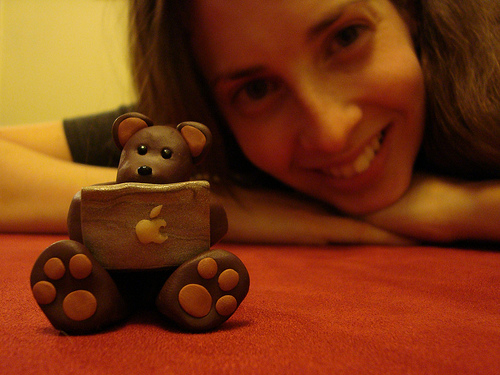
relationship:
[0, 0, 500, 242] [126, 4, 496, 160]
girl has hair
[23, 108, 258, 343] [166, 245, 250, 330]
bear has foot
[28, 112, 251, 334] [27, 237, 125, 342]
bear has foot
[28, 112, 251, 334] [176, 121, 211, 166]
bear has ceramic ear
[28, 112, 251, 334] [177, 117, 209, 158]
bear has ceramic ear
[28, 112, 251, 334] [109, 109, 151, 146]
bear has ceramic ear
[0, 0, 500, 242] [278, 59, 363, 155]
girl has nose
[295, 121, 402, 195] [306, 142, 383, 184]
mouth with teeth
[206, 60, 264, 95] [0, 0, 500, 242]
eyebrow of girl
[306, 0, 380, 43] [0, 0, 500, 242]
eyebrow of girl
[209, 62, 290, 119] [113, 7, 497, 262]
eye of woman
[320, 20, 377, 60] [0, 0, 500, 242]
eye of girl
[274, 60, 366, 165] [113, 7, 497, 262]
nose of woman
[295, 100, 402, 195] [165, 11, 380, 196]
mouth of woman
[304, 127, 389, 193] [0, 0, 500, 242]
teeth of girl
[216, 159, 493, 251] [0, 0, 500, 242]
hands of girl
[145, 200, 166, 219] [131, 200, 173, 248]
leaf of apple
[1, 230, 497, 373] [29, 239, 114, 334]
fabric under big feet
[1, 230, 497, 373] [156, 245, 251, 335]
fabric under feet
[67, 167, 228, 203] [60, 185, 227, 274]
edge on cover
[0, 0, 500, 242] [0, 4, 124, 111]
girl in front of wall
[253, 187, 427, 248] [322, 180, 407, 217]
hands positioned under chin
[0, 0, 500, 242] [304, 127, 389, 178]
girl smiling and showing teeth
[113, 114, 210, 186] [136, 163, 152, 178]
beady eyes over black nose